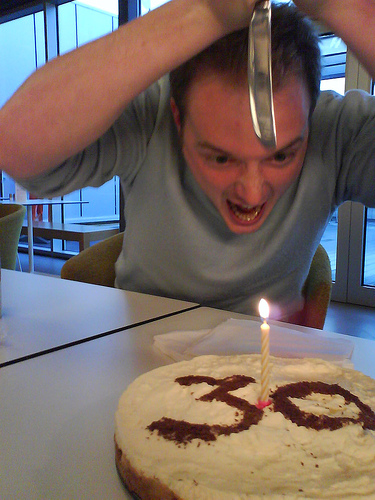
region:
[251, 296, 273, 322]
Flame on top of a candle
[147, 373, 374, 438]
Number thirty on a cake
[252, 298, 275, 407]
lit birthday candle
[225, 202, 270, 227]
The mans open mouth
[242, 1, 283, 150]
Silver knife point down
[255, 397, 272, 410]
pink frosting at the bottom of the candle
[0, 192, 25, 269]
Side of green chair on the left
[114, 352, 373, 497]
A round birthday cake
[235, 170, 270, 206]
Man's nose pointed down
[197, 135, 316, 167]
Mans eyes that are looking down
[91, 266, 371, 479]
a cake with candle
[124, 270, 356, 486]
a cake with candle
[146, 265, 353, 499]
a cake with candle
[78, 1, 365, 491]
man ready to stab the cake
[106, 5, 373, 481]
man ready to stab the cake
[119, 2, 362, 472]
man ready to stab the cake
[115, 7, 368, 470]
man ready to stab the cake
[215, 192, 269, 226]
mouth opened up with teeth showing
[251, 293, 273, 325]
open flame on top of candle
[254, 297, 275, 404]
yellow and white single birthday candle lit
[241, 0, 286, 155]
silver colored knife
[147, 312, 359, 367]
napkin laying on table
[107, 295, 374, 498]
birthday cake with white frosting and number 30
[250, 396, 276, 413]
pink plastic piece in cake to hold candle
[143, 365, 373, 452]
brown number 30 in brown frosting on top of white frosting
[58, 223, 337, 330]
green upholstered table chair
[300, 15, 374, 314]
silver sliding glass doors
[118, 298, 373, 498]
the number "30" on a cake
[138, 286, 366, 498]
a lit candle on a cake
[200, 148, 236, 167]
an eye of a man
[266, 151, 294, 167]
an eye of a man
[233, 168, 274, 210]
the nose of a man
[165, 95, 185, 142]
the ear of a man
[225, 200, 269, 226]
the mouth of a man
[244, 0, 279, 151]
a cake cutting knife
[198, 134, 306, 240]
the face of a man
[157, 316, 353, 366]
a white napkin on a table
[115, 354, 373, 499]
Number 30 is on a cake.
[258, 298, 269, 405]
A candle is lit.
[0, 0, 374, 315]
A man is holding a knife.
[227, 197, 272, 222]
An open mouth has white teeth.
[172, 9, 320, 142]
A man has short brown hair.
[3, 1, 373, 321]
Windows and a glass door are behind a man.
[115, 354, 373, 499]
A cake is brown and white.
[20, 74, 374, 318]
The man is wearing a gray shirt.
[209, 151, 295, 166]
Two eyes are open.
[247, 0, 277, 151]
The silver knife had a rounded tip.